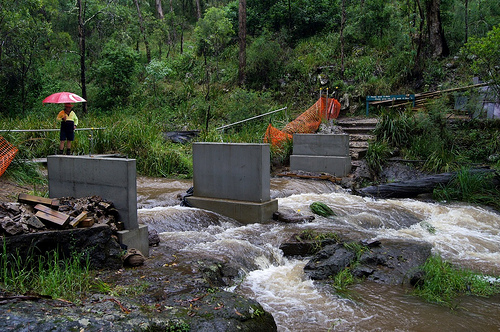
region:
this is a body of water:
[244, 251, 342, 318]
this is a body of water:
[426, 199, 499, 271]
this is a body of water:
[285, 169, 370, 234]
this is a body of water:
[194, 222, 279, 259]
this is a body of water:
[39, 90, 89, 111]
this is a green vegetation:
[94, 34, 180, 145]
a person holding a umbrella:
[44, 89, 84, 149]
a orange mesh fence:
[260, 98, 341, 145]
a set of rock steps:
[348, 113, 380, 163]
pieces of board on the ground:
[17, 191, 88, 232]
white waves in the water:
[378, 196, 491, 294]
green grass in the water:
[420, 247, 491, 312]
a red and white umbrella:
[41, 91, 91, 108]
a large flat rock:
[96, 292, 283, 329]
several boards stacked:
[376, 84, 445, 117]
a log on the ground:
[363, 173, 493, 200]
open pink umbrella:
[32, 85, 93, 109]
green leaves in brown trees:
[146, 49, 186, 73]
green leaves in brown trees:
[296, 58, 310, 70]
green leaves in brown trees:
[176, 23, 203, 44]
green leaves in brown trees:
[140, 88, 170, 112]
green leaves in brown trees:
[152, 51, 206, 81]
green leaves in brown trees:
[110, 48, 145, 76]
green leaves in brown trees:
[255, 39, 286, 57]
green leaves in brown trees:
[169, 45, 200, 85]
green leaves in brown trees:
[200, 48, 241, 85]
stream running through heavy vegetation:
[11, 14, 490, 319]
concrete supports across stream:
[52, 130, 360, 232]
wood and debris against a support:
[3, 150, 138, 275]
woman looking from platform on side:
[5, 81, 118, 165]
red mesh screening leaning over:
[259, 88, 341, 164]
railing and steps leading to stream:
[329, 72, 494, 184]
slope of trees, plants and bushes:
[7, 8, 499, 185]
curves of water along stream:
[154, 189, 494, 321]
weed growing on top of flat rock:
[7, 252, 272, 328]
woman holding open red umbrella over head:
[43, 92, 85, 124]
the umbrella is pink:
[39, 83, 90, 156]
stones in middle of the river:
[231, 185, 449, 320]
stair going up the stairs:
[328, 63, 498, 178]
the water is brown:
[143, 165, 498, 325]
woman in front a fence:
[1, 86, 121, 163]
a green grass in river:
[213, 163, 496, 328]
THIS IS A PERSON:
[40, 85, 90, 151]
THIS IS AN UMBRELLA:
[38, 80, 90, 107]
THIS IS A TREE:
[229, 0, 251, 79]